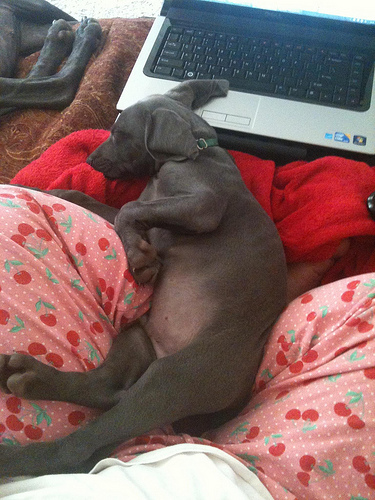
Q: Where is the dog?
A: Bed.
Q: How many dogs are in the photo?
A: Two.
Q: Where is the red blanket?
A: Under puppy.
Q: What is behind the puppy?
A: Laptop.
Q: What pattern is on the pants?
A: Cherries.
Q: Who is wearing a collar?
A: Puppy.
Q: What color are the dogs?
A: Brown.